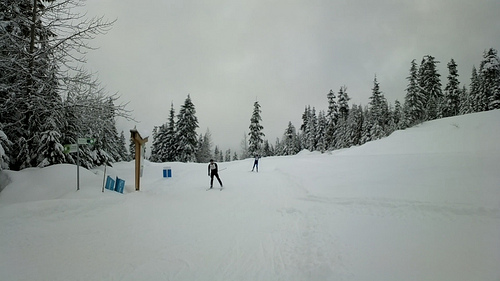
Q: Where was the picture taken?
A: Ski slope.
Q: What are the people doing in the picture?
A: Skiing.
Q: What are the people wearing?
A: Snowsuits.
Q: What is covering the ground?
A: Snow.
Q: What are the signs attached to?
A: A pole.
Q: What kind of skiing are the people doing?
A: Cross country.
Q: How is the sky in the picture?
A: Cloudy.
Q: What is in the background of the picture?
A: Pine trees.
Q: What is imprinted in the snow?
A: Ski tracks.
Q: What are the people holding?
A: Ski poles.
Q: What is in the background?
A: Trees.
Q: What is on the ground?
A: Snow.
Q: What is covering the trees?
A: Snow.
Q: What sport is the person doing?
A: Skiing.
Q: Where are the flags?
A: On the left.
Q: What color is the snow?
A: White.